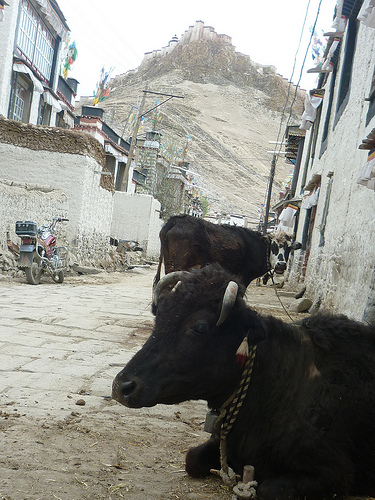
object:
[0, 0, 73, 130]
building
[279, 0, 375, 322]
building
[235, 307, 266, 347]
cow's ear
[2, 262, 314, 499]
road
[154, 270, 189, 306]
horns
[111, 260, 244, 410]
head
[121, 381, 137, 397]
nostril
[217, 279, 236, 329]
horn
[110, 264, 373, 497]
bull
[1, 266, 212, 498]
street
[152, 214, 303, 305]
bull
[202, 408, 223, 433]
bell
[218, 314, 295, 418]
neck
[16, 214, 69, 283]
motorcycle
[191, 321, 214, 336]
eye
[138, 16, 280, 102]
mountain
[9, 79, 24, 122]
window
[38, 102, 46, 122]
window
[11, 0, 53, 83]
window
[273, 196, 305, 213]
banners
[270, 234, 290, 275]
cow face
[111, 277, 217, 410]
face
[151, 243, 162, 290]
tail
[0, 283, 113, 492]
ground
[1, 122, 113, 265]
building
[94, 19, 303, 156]
hill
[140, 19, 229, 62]
buildings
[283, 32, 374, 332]
side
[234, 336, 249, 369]
tag